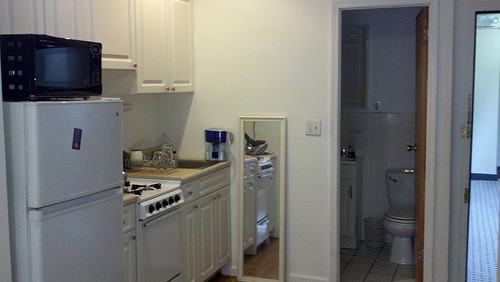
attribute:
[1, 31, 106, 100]
microwave — black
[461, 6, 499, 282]
mirror — full length, leaning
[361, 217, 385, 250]
wastebasket — in bathroom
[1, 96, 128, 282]
refrigerator — white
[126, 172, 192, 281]
stove — white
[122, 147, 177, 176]
rack — for dishes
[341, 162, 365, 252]
cabinet — white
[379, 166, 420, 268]
toilet — white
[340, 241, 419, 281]
floor — tiled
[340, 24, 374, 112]
mirror — on wall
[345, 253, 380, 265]
tile — in bathroom